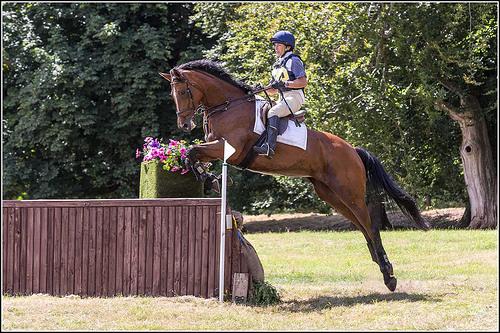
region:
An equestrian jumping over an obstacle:
[158, 31, 430, 291]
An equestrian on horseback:
[253, 25, 318, 165]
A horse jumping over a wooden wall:
[156, 60, 433, 294]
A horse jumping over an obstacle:
[158, 61, 429, 294]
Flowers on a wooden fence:
[5, 138, 187, 291]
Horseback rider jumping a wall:
[159, 20, 431, 293]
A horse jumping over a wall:
[156, 30, 431, 294]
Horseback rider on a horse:
[195, 20, 358, 157]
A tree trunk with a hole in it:
[418, 120, 498, 226]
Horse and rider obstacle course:
[157, 60, 432, 295]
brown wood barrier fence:
[1, 196, 223, 298]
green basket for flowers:
[138, 163, 207, 198]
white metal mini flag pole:
[221, 164, 225, 301]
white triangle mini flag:
[224, 142, 236, 162]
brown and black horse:
[170, 62, 419, 299]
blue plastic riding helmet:
[273, 29, 298, 49]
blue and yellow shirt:
[271, 58, 304, 93]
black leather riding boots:
[256, 114, 280, 160]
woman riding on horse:
[250, 30, 311, 153]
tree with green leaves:
[232, 5, 495, 226]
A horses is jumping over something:
[68, 17, 455, 312]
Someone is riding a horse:
[102, 16, 472, 301]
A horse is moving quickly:
[125, 12, 445, 307]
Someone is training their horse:
[110, 12, 445, 314]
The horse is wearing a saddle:
[95, 11, 466, 313]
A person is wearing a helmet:
[130, 20, 450, 295]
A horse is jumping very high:
[110, 25, 460, 310]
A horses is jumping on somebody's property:
[45, 16, 480, 307]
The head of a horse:
[171, 65, 196, 125]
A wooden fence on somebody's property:
[6, 200, 214, 296]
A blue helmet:
[269, 30, 298, 50]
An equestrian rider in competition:
[136, 14, 421, 300]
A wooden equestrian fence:
[58, 197, 228, 298]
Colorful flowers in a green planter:
[136, 132, 217, 175]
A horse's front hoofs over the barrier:
[162, 133, 226, 295]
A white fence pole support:
[216, 161, 229, 305]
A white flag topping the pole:
[211, 133, 238, 172]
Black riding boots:
[255, 115, 282, 159]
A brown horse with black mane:
[163, 61, 298, 179]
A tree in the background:
[372, 28, 498, 231]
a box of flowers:
[135, 131, 217, 201]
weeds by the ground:
[247, 269, 282, 311]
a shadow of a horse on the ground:
[280, 270, 430, 322]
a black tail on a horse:
[359, 150, 428, 222]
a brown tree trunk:
[445, 78, 499, 233]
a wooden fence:
[0, 193, 220, 297]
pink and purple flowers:
[139, 137, 208, 171]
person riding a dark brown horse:
[152, 33, 405, 278]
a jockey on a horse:
[245, 22, 322, 159]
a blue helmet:
[267, 25, 298, 50]